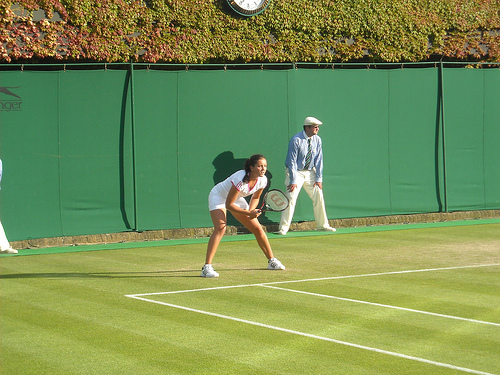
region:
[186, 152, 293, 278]
woman playing tennis with racquet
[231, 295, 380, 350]
white lines on a tennis court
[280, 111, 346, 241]
man watching the tennis match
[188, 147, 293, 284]
woman in ready position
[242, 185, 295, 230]
wilson brand tennis racquet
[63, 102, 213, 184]
green canvas around the tennis court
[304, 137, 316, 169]
striped tie on a man's neck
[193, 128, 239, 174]
shadow of a man on the canvas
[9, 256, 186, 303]
elongated shadow of the tennis player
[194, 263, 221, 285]
white tennis shoes on tennis court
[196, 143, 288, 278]
a woman bent over.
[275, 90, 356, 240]
a well dressed man.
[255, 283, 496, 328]
a white line on a tennis court.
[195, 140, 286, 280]
a woman playing tennis.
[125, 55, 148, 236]
a green pole on a tennis court.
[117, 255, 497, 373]
an outline for a tennis court.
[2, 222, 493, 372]
a lush green tennis court.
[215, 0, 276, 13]
a clock on ivy.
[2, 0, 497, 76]
a large green bush.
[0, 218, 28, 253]
a person's leg.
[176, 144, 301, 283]
a woman playing tennis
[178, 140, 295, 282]
a woman holding a tennis racket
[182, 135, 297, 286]
a woman dressed in white tennis gear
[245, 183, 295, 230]
a tennis racket with a red "w"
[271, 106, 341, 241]
A man with a white hat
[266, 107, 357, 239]
A man wearing a green tie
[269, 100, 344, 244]
A man wearing white pants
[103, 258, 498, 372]
A tennis court with painted lines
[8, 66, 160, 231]
A green wall with metal framing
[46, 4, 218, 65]
red and green growing vines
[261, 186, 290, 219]
"W" on the racket.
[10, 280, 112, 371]
The grass is green.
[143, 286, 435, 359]
White lines on the court.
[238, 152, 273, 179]
The girl has brown hair.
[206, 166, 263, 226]
The uniform is white.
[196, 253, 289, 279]
The shoes are white.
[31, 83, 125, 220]
The background is green.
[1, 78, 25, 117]
Logo on the wall.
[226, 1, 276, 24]
Bottom of a clock.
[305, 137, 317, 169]
Man is wearing a tie.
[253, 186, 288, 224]
a black tennis racket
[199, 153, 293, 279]
a woman holding a black racket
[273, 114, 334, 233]
a man in a blue shirt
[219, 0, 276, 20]
a clock on the bushes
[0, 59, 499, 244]
a tall green fence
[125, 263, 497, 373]
white tennis court lines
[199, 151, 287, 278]
a woman wearing all white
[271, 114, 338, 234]
a man in a white hat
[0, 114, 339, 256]
two tennis referees